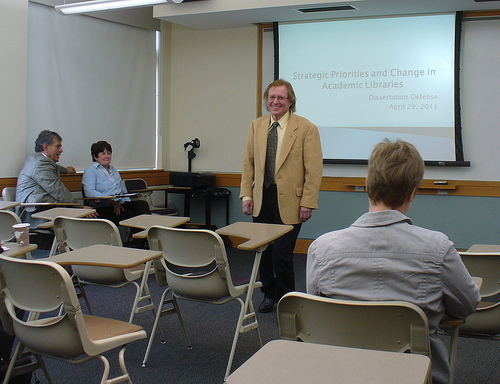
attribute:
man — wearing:
[231, 75, 328, 322]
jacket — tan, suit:
[248, 112, 315, 218]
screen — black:
[276, 12, 464, 165]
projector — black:
[160, 162, 216, 189]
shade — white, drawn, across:
[26, 2, 156, 171]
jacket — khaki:
[236, 112, 323, 223]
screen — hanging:
[260, 12, 480, 175]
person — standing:
[242, 80, 312, 311]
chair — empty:
[147, 227, 280, 338]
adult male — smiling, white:
[237, 67, 324, 298]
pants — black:
[266, 188, 306, 298]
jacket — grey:
[319, 197, 473, 330]